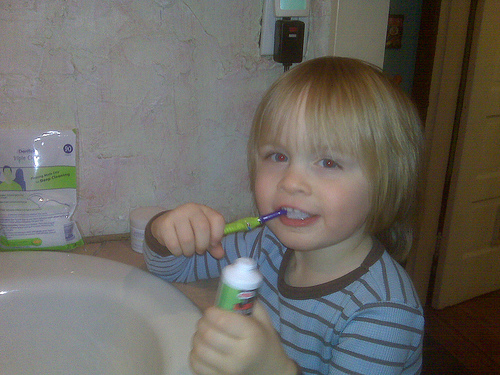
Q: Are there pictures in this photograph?
A: No, there are no pictures.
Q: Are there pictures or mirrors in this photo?
A: No, there are no pictures or mirrors.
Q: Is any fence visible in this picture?
A: No, there are no fences.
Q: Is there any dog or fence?
A: No, there are no fences or dogs.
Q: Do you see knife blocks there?
A: No, there are no knife blocks.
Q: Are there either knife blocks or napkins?
A: No, there are no knife blocks or napkins.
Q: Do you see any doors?
A: Yes, there is a door.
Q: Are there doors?
A: Yes, there is a door.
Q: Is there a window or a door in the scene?
A: Yes, there is a door.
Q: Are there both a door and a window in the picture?
A: No, there is a door but no windows.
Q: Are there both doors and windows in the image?
A: No, there is a door but no windows.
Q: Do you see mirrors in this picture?
A: No, there are no mirrors.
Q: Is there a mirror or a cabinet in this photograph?
A: No, there are no mirrors or cabinets.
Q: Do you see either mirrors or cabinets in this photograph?
A: No, there are no mirrors or cabinets.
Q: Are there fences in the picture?
A: No, there are no fences.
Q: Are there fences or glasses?
A: No, there are no fences or glasses.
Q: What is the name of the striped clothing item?
A: The clothing item is a shirt.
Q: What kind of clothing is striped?
A: The clothing is a shirt.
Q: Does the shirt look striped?
A: Yes, the shirt is striped.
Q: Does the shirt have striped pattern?
A: Yes, the shirt is striped.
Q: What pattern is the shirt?
A: The shirt is striped.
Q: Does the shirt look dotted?
A: No, the shirt is striped.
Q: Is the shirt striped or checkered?
A: The shirt is striped.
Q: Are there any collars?
A: Yes, there is a collar.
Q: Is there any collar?
A: Yes, there is a collar.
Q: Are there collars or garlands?
A: Yes, there is a collar.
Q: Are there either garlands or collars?
A: Yes, there is a collar.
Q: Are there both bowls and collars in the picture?
A: No, there is a collar but no bowls.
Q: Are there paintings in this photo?
A: No, there are no paintings.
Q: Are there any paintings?
A: No, there are no paintings.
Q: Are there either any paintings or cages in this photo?
A: No, there are no paintings or cages.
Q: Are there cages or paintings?
A: No, there are no paintings or cages.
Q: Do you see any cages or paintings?
A: No, there are no paintings or cages.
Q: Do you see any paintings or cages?
A: No, there are no paintings or cages.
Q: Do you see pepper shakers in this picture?
A: No, there are no pepper shakers.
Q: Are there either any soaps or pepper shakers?
A: No, there are no pepper shakers or soaps.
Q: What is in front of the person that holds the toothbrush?
A: The sink is in front of the boy.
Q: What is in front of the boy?
A: The sink is in front of the boy.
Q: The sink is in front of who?
A: The sink is in front of the boy.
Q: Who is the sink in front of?
A: The sink is in front of the boy.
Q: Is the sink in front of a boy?
A: Yes, the sink is in front of a boy.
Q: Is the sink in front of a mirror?
A: No, the sink is in front of a boy.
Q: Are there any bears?
A: No, there are no bears.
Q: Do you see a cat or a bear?
A: No, there are no bears or cats.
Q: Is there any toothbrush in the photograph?
A: Yes, there is a toothbrush.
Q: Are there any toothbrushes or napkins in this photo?
A: Yes, there is a toothbrush.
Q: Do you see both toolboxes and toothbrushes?
A: No, there is a toothbrush but no toolboxes.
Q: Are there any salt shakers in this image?
A: No, there are no salt shakers.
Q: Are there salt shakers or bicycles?
A: No, there are no salt shakers or bicycles.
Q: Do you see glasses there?
A: No, there are no glasses.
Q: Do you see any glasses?
A: No, there are no glasses.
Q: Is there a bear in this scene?
A: No, there are no bears.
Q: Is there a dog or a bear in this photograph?
A: No, there are no bears or dogs.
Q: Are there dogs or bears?
A: No, there are no bears or dogs.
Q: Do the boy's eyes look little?
A: Yes, the eyes are little.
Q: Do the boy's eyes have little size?
A: Yes, the eyes are little.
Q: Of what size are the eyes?
A: The eyes are little.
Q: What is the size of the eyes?
A: The eyes are little.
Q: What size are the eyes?
A: The eyes are little.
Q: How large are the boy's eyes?
A: The eyes are little.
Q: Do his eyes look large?
A: No, the eyes are little.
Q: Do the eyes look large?
A: No, the eyes are little.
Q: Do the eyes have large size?
A: No, the eyes are little.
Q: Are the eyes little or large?
A: The eyes are little.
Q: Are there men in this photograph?
A: No, there are no men.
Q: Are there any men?
A: No, there are no men.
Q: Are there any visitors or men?
A: No, there are no men or visitors.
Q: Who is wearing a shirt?
A: The boy is wearing a shirt.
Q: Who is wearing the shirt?
A: The boy is wearing a shirt.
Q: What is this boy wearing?
A: The boy is wearing a shirt.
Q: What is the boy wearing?
A: The boy is wearing a shirt.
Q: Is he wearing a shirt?
A: Yes, the boy is wearing a shirt.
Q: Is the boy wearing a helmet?
A: No, the boy is wearing a shirt.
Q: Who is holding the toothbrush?
A: The boy is holding the toothbrush.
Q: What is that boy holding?
A: The boy is holding the toothbrush.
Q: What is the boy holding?
A: The boy is holding the toothbrush.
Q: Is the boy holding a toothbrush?
A: Yes, the boy is holding a toothbrush.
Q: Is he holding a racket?
A: No, the boy is holding a toothbrush.